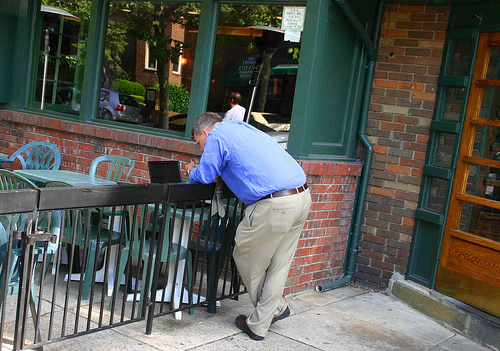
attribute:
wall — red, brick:
[355, 6, 454, 282]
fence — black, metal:
[2, 190, 254, 329]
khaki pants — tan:
[239, 199, 300, 330]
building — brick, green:
[3, 2, 500, 274]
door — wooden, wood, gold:
[451, 34, 500, 309]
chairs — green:
[10, 145, 55, 215]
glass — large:
[26, 3, 319, 137]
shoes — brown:
[230, 313, 264, 341]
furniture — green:
[0, 135, 205, 302]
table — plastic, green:
[22, 165, 109, 188]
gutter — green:
[338, 4, 387, 57]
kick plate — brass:
[439, 267, 500, 302]